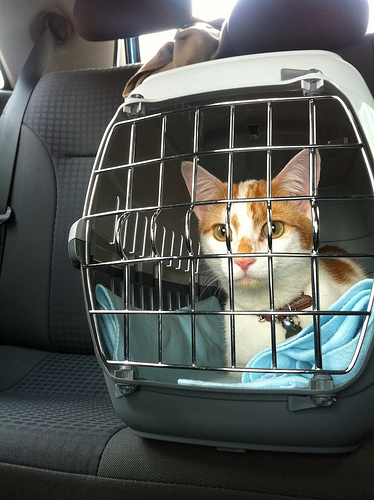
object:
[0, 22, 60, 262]
seat belt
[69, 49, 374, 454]
crate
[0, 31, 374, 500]
seat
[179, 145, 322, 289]
head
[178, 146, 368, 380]
cat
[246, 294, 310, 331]
collar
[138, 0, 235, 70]
window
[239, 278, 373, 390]
blue blanket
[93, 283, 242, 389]
blanket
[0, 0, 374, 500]
car